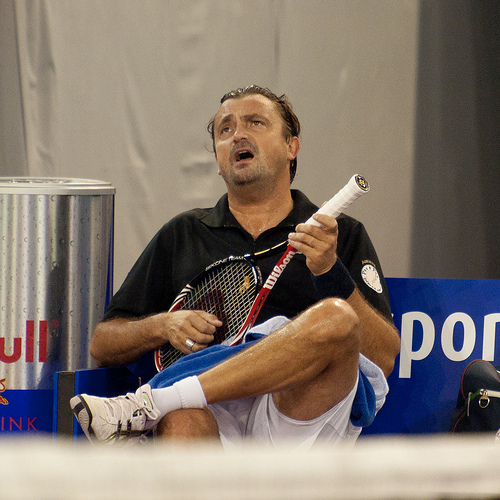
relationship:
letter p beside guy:
[398, 309, 436, 379] [68, 84, 403, 448]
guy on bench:
[68, 84, 403, 448] [1, 429, 498, 499]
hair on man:
[205, 84, 305, 133] [66, 88, 391, 497]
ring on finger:
[181, 332, 199, 350] [168, 325, 208, 355]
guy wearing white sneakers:
[68, 84, 403, 448] [69, 382, 164, 446]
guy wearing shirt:
[68, 84, 403, 448] [101, 186, 399, 376]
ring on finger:
[184, 338, 196, 350] [173, 331, 205, 351]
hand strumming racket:
[158, 306, 230, 355] [152, 170, 369, 378]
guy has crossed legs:
[68, 84, 403, 448] [125, 306, 343, 375]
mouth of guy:
[232, 146, 264, 165] [70, 84, 398, 456]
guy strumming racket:
[70, 84, 398, 456] [153, 172, 372, 374]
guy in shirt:
[70, 84, 398, 456] [106, 193, 411, 364]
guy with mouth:
[70, 84, 398, 456] [216, 135, 264, 169]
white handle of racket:
[301, 168, 368, 243] [153, 172, 372, 374]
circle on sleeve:
[362, 264, 382, 294] [348, 220, 396, 325]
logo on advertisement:
[1, 319, 53, 436] [14, 175, 144, 466]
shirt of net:
[99, 188, 398, 385] [1, 430, 497, 500]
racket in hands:
[139, 168, 379, 377] [157, 208, 349, 362]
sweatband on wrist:
[311, 261, 359, 300] [309, 248, 339, 278]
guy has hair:
[68, 84, 403, 448] [191, 69, 321, 199]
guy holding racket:
[68, 84, 403, 448] [152, 170, 369, 378]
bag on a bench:
[451, 355, 499, 428] [42, 244, 496, 484]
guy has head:
[68, 84, 403, 448] [190, 60, 314, 203]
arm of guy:
[94, 311, 165, 363] [68, 84, 403, 448]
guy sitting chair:
[68, 84, 403, 448] [185, 312, 286, 444]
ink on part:
[62, 288, 123, 444] [29, 328, 47, 420]